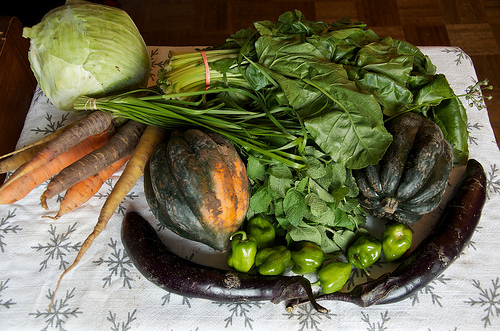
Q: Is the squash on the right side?
A: Yes, the squash is on the right of the image.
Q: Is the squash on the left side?
A: No, the squash is on the right of the image.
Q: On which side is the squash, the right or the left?
A: The squash is on the right of the image.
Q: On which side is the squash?
A: The squash is on the right of the image.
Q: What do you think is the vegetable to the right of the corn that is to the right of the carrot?
A: The vegetable is a squash.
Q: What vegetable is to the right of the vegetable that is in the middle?
A: The vegetable is a squash.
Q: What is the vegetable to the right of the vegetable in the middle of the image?
A: The vegetable is a squash.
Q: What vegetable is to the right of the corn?
A: The vegetable is a squash.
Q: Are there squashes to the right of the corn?
A: Yes, there is a squash to the right of the corn.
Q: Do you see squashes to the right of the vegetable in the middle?
A: Yes, there is a squash to the right of the corn.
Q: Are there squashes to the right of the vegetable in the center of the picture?
A: Yes, there is a squash to the right of the corn.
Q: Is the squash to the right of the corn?
A: Yes, the squash is to the right of the corn.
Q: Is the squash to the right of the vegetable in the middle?
A: Yes, the squash is to the right of the corn.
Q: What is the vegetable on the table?
A: The vegetable is a squash.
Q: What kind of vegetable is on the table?
A: The vegetable is a squash.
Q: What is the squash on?
A: The squash is on the table.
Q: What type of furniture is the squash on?
A: The squash is on the table.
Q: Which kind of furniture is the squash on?
A: The squash is on the table.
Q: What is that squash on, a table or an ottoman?
A: The squash is on a table.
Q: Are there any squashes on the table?
A: Yes, there is a squash on the table.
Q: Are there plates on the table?
A: No, there is a squash on the table.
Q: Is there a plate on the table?
A: No, there is a squash on the table.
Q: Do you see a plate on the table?
A: No, there is a squash on the table.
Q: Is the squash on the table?
A: Yes, the squash is on the table.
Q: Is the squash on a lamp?
A: No, the squash is on the table.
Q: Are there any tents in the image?
A: No, there are no tents.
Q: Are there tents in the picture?
A: No, there are no tents.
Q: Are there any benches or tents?
A: No, there are no tents or benches.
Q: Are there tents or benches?
A: No, there are no tents or benches.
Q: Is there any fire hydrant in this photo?
A: No, there are no fire hydrants.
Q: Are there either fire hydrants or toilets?
A: No, there are no fire hydrants or toilets.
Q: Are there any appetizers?
A: No, there are no appetizers.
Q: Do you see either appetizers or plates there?
A: No, there are no appetizers or plates.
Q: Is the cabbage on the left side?
A: Yes, the cabbage is on the left of the image.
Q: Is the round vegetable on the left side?
A: Yes, the cabbage is on the left of the image.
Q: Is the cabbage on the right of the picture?
A: No, the cabbage is on the left of the image.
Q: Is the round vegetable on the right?
A: No, the cabbage is on the left of the image.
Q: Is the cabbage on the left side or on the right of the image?
A: The cabbage is on the left of the image.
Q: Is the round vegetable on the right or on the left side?
A: The cabbage is on the left of the image.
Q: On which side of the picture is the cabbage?
A: The cabbage is on the left of the image.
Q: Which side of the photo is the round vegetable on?
A: The cabbage is on the left of the image.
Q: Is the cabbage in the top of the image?
A: Yes, the cabbage is in the top of the image.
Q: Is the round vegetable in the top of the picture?
A: Yes, the cabbage is in the top of the image.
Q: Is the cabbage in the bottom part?
A: No, the cabbage is in the top of the image.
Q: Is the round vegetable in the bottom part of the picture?
A: No, the cabbage is in the top of the image.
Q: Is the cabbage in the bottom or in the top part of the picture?
A: The cabbage is in the top of the image.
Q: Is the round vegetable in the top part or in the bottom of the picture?
A: The cabbage is in the top of the image.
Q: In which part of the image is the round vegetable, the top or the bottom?
A: The cabbage is in the top of the image.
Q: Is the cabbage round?
A: Yes, the cabbage is round.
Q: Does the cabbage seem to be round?
A: Yes, the cabbage is round.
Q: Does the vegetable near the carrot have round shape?
A: Yes, the cabbage is round.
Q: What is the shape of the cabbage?
A: The cabbage is round.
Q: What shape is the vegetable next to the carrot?
A: The cabbage is round.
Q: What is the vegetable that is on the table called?
A: The vegetable is a cabbage.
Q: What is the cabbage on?
A: The cabbage is on the table.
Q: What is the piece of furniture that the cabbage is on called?
A: The piece of furniture is a table.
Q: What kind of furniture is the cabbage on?
A: The cabbage is on the table.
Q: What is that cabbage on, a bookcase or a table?
A: The cabbage is on a table.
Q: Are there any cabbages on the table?
A: Yes, there is a cabbage on the table.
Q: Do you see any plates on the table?
A: No, there is a cabbage on the table.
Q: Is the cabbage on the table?
A: Yes, the cabbage is on the table.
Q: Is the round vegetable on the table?
A: Yes, the cabbage is on the table.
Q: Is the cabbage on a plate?
A: No, the cabbage is on the table.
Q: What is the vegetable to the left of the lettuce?
A: The vegetable is a cabbage.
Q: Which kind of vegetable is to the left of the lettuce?
A: The vegetable is a cabbage.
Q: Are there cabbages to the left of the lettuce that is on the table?
A: Yes, there is a cabbage to the left of the lettuce.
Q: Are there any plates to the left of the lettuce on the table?
A: No, there is a cabbage to the left of the lettuce.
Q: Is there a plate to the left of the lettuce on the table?
A: No, there is a cabbage to the left of the lettuce.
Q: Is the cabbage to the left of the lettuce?
A: Yes, the cabbage is to the left of the lettuce.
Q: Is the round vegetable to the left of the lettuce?
A: Yes, the cabbage is to the left of the lettuce.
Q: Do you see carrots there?
A: Yes, there is a carrot.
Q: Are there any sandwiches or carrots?
A: Yes, there is a carrot.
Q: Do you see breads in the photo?
A: No, there are no breads.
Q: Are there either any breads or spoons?
A: No, there are no breads or spoons.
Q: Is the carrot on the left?
A: Yes, the carrot is on the left of the image.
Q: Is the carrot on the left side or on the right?
A: The carrot is on the left of the image.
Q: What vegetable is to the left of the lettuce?
A: The vegetable is a carrot.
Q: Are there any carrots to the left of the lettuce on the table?
A: Yes, there is a carrot to the left of the lettuce.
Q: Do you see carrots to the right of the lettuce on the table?
A: No, the carrot is to the left of the lettuce.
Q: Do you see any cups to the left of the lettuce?
A: No, there is a carrot to the left of the lettuce.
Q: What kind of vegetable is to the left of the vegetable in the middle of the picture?
A: The vegetable is a carrot.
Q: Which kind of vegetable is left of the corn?
A: The vegetable is a carrot.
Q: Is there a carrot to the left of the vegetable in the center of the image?
A: Yes, there is a carrot to the left of the corn.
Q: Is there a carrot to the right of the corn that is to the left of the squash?
A: No, the carrot is to the left of the corn.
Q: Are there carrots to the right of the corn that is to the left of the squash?
A: No, the carrot is to the left of the corn.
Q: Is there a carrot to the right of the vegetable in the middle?
A: No, the carrot is to the left of the corn.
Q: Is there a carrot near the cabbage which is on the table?
A: Yes, there is a carrot near the cabbage.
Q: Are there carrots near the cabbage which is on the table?
A: Yes, there is a carrot near the cabbage.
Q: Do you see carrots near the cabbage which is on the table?
A: Yes, there is a carrot near the cabbage.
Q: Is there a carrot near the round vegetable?
A: Yes, there is a carrot near the cabbage.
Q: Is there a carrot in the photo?
A: Yes, there are carrots.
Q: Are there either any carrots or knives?
A: Yes, there are carrots.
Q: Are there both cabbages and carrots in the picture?
A: Yes, there are both carrots and a cabbage.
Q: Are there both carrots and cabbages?
A: Yes, there are both carrots and a cabbage.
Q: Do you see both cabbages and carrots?
A: Yes, there are both carrots and a cabbage.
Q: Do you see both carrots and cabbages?
A: Yes, there are both carrots and a cabbage.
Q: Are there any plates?
A: No, there are no plates.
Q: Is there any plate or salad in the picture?
A: No, there are no plates or salad.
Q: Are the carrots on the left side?
A: Yes, the carrots are on the left of the image.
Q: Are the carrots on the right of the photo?
A: No, the carrots are on the left of the image.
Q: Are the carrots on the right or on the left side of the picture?
A: The carrots are on the left of the image.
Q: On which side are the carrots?
A: The carrots are on the left of the image.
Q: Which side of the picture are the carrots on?
A: The carrots are on the left of the image.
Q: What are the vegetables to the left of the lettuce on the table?
A: The vegetables are carrots.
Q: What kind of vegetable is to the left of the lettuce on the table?
A: The vegetables are carrots.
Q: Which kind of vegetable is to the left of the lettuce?
A: The vegetables are carrots.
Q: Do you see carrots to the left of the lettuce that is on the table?
A: Yes, there are carrots to the left of the lettuce.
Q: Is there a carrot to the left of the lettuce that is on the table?
A: Yes, there are carrots to the left of the lettuce.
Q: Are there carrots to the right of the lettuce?
A: No, the carrots are to the left of the lettuce.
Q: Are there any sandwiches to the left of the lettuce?
A: No, there are carrots to the left of the lettuce.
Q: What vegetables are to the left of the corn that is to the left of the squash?
A: The vegetables are carrots.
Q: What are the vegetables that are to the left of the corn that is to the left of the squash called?
A: The vegetables are carrots.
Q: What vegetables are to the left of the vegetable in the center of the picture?
A: The vegetables are carrots.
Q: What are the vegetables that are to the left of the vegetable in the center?
A: The vegetables are carrots.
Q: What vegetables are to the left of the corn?
A: The vegetables are carrots.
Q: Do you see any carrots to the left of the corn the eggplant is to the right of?
A: Yes, there are carrots to the left of the corn.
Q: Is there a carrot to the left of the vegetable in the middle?
A: Yes, there are carrots to the left of the corn.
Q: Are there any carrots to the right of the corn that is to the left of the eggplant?
A: No, the carrots are to the left of the corn.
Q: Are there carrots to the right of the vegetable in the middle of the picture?
A: No, the carrots are to the left of the corn.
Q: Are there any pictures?
A: No, there are no pictures.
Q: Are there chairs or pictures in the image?
A: No, there are no pictures or chairs.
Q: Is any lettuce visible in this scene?
A: Yes, there is lettuce.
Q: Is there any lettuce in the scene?
A: Yes, there is lettuce.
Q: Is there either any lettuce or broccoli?
A: Yes, there is lettuce.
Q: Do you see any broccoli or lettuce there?
A: Yes, there is lettuce.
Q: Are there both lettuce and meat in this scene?
A: No, there is lettuce but no meat.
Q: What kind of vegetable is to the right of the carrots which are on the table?
A: The vegetable is lettuce.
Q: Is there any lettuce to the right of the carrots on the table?
A: Yes, there is lettuce to the right of the carrots.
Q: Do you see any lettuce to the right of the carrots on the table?
A: Yes, there is lettuce to the right of the carrots.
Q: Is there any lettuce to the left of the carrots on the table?
A: No, the lettuce is to the right of the carrots.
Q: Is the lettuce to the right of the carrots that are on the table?
A: Yes, the lettuce is to the right of the carrots.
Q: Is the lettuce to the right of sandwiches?
A: No, the lettuce is to the right of the carrots.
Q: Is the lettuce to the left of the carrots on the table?
A: No, the lettuce is to the right of the carrots.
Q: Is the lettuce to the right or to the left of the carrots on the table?
A: The lettuce is to the right of the carrots.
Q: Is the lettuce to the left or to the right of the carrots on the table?
A: The lettuce is to the right of the carrots.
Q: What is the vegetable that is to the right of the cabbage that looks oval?
A: The vegetable is lettuce.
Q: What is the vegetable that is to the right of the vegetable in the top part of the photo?
A: The vegetable is lettuce.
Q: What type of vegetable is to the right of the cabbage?
A: The vegetable is lettuce.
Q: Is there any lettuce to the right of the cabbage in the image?
A: Yes, there is lettuce to the right of the cabbage.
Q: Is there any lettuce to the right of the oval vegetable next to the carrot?
A: Yes, there is lettuce to the right of the cabbage.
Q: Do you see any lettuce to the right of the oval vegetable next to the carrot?
A: Yes, there is lettuce to the right of the cabbage.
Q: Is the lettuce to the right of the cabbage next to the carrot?
A: Yes, the lettuce is to the right of the cabbage.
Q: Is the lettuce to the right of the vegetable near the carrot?
A: Yes, the lettuce is to the right of the cabbage.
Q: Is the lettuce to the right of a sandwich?
A: No, the lettuce is to the right of the cabbage.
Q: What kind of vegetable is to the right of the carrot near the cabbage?
A: The vegetable is lettuce.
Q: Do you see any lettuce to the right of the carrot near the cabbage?
A: Yes, there is lettuce to the right of the carrot.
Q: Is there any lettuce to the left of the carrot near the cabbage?
A: No, the lettuce is to the right of the carrot.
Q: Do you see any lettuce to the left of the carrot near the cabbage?
A: No, the lettuce is to the right of the carrot.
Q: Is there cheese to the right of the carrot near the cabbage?
A: No, there is lettuce to the right of the carrot.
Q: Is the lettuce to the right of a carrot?
A: Yes, the lettuce is to the right of a carrot.